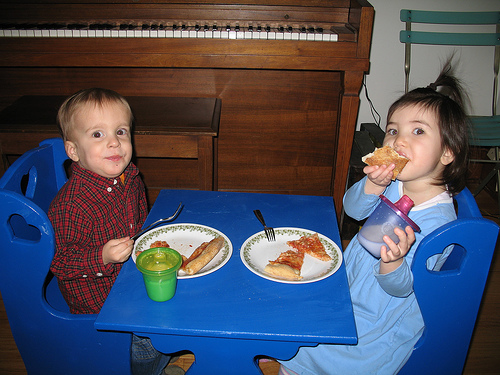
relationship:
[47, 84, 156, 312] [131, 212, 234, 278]
boy eating lunch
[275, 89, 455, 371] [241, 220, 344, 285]
girl eating lunch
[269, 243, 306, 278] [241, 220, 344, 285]
pizza on plate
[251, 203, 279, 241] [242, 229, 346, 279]
fork on plate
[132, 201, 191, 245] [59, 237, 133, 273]
fork in boyshand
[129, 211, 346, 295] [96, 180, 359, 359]
plates on table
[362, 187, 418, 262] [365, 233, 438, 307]
sipycup in grilshand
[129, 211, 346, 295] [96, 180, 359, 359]
two plates on table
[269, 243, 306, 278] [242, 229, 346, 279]
pizza on plate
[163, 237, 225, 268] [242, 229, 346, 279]
hotdog on plate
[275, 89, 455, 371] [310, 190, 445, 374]
girl wearing blue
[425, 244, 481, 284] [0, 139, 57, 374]
heart on chair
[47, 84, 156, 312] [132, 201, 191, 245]
boy holding fork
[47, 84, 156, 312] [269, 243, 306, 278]
boy eating pizza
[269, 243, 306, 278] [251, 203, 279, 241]
pizza with fork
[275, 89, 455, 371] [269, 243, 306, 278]
girl eating pizza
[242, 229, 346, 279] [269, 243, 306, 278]
toddelrs eating pizza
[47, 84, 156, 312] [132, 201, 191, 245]
children holding fork